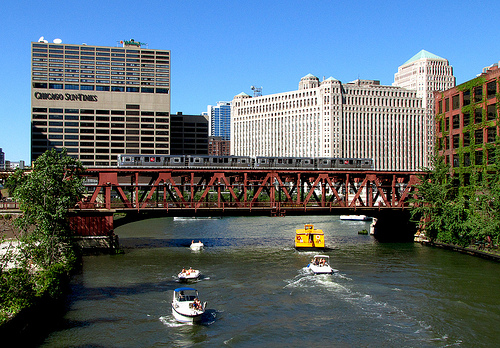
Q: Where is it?
A: This is at the river.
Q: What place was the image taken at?
A: It was taken at the river.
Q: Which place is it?
A: It is a river.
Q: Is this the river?
A: Yes, it is the river.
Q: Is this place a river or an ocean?
A: It is a river.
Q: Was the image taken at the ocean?
A: No, the picture was taken in the river.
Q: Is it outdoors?
A: Yes, it is outdoors.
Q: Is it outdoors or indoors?
A: It is outdoors.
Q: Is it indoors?
A: No, it is outdoors.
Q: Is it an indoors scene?
A: No, it is outdoors.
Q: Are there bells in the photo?
A: No, there are no bells.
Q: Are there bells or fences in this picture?
A: No, there are no bells or fences.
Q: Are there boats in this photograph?
A: Yes, there is a boat.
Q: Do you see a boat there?
A: Yes, there is a boat.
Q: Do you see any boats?
A: Yes, there is a boat.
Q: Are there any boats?
A: Yes, there is a boat.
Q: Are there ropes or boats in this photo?
A: Yes, there is a boat.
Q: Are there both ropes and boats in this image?
A: No, there is a boat but no ropes.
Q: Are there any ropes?
A: No, there are no ropes.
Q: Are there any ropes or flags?
A: No, there are no ropes or flags.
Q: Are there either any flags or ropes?
A: No, there are no ropes or flags.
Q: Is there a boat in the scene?
A: Yes, there is a boat.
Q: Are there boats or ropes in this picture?
A: Yes, there is a boat.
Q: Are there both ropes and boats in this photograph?
A: No, there is a boat but no ropes.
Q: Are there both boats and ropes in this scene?
A: No, there is a boat but no ropes.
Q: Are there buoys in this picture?
A: No, there are no buoys.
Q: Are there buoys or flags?
A: No, there are no buoys or flags.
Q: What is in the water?
A: The boat is in the water.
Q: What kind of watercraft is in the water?
A: The watercraft is a boat.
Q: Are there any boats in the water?
A: Yes, there is a boat in the water.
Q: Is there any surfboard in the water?
A: No, there is a boat in the water.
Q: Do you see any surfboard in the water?
A: No, there is a boat in the water.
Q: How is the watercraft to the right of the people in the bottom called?
A: The watercraft is a boat.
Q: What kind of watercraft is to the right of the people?
A: The watercraft is a boat.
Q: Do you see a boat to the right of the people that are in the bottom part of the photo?
A: Yes, there is a boat to the right of the people.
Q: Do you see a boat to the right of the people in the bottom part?
A: Yes, there is a boat to the right of the people.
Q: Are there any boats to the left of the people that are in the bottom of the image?
A: No, the boat is to the right of the people.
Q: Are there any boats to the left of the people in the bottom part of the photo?
A: No, the boat is to the right of the people.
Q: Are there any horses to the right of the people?
A: No, there is a boat to the right of the people.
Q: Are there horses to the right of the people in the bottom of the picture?
A: No, there is a boat to the right of the people.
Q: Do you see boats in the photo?
A: Yes, there is a boat.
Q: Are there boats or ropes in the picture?
A: Yes, there is a boat.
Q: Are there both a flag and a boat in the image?
A: No, there is a boat but no flags.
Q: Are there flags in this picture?
A: No, there are no flags.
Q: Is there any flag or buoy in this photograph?
A: No, there are no flags or buoys.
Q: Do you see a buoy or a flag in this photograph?
A: No, there are no flags or buoys.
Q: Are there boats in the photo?
A: Yes, there is a boat.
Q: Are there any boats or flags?
A: Yes, there is a boat.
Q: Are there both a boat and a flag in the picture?
A: No, there is a boat but no flags.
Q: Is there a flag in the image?
A: No, there are no flags.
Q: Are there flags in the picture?
A: No, there are no flags.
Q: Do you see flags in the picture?
A: No, there are no flags.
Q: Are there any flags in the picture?
A: No, there are no flags.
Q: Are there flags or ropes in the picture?
A: No, there are no flags or ropes.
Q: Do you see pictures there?
A: No, there are no pictures.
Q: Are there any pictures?
A: No, there are no pictures.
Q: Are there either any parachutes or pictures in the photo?
A: No, there are no pictures or parachutes.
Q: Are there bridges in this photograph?
A: Yes, there is a bridge.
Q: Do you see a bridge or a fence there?
A: Yes, there is a bridge.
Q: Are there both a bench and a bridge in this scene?
A: No, there is a bridge but no benches.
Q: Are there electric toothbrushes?
A: No, there are no electric toothbrushes.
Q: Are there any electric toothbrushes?
A: No, there are no electric toothbrushes.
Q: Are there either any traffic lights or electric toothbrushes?
A: No, there are no electric toothbrushes or traffic lights.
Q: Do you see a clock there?
A: No, there are no clocks.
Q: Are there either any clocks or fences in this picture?
A: No, there are no clocks or fences.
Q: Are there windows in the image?
A: Yes, there are windows.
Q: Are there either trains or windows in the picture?
A: Yes, there are windows.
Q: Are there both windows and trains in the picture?
A: Yes, there are both windows and a train.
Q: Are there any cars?
A: No, there are no cars.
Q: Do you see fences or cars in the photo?
A: No, there are no cars or fences.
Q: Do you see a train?
A: Yes, there is a train.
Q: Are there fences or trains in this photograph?
A: Yes, there is a train.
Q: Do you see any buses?
A: No, there are no buses.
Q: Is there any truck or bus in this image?
A: No, there are no buses or trucks.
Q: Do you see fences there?
A: No, there are no fences.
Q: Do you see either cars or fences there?
A: No, there are no fences or cars.